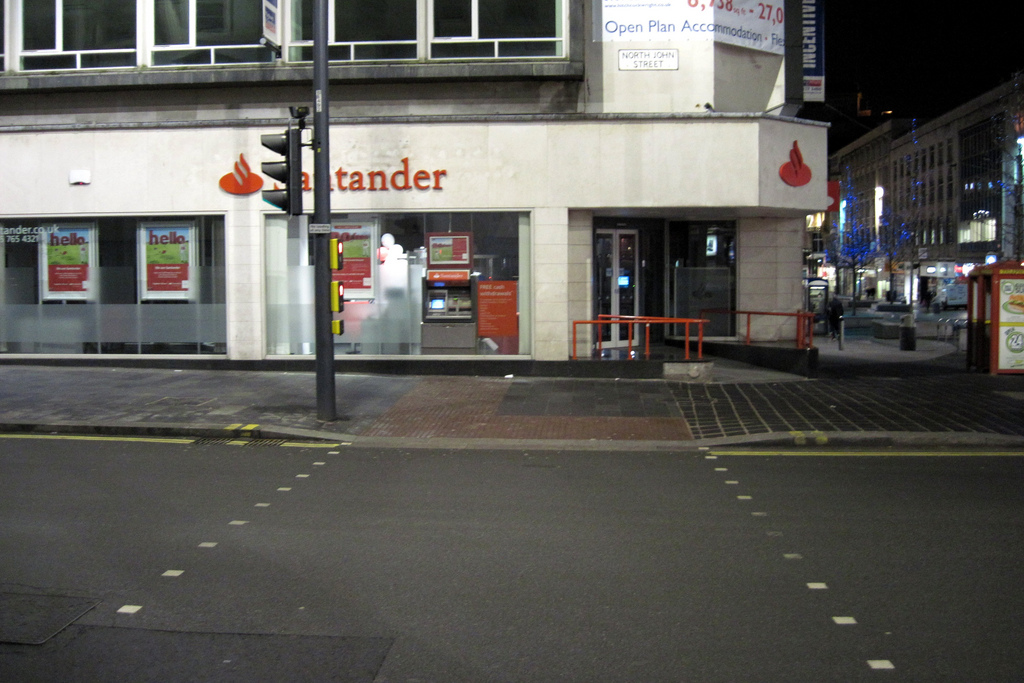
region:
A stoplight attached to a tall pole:
[253, 119, 305, 225]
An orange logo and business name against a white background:
[209, 149, 453, 200]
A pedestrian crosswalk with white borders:
[133, 430, 909, 672]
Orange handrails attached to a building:
[573, 310, 713, 371]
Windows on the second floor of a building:
[2, 1, 573, 60]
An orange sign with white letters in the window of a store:
[471, 274, 519, 354]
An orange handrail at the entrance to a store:
[716, 301, 825, 355]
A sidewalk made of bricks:
[0, 354, 1022, 452]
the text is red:
[280, 156, 446, 191]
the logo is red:
[779, 140, 809, 188]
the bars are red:
[563, 314, 701, 359]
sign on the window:
[137, 227, 195, 298]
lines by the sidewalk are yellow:
[122, 419, 315, 473]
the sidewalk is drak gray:
[48, 361, 368, 425]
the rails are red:
[589, 298, 736, 390]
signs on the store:
[38, 220, 234, 341]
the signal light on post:
[251, 98, 356, 269]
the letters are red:
[216, 137, 474, 214]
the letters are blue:
[601, 17, 778, 49]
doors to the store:
[594, 224, 665, 345]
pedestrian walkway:
[109, 440, 894, 679]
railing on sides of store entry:
[573, 307, 833, 353]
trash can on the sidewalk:
[891, 320, 921, 353]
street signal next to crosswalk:
[263, 118, 306, 223]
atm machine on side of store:
[418, 272, 475, 358]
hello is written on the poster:
[141, 223, 198, 247]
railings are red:
[564, 307, 703, 371]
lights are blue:
[832, 172, 882, 272]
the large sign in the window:
[35, 216, 100, 308]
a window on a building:
[20, 2, 56, 54]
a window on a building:
[55, 1, 154, 52]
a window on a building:
[143, 7, 189, 49]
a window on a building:
[189, 4, 288, 39]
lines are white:
[718, 429, 875, 655]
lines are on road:
[718, 418, 922, 678]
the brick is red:
[691, 370, 925, 459]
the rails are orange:
[556, 278, 835, 383]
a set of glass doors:
[559, 209, 676, 380]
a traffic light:
[249, 85, 349, 237]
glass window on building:
[25, 54, 79, 71]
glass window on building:
[79, 48, 137, 65]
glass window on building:
[151, 45, 216, 62]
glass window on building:
[217, 42, 276, 61]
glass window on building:
[354, 42, 413, 56]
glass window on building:
[432, 44, 499, 55]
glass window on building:
[499, 41, 556, 58]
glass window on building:
[479, 3, 559, 42]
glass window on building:
[433, 0, 478, 42]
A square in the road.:
[830, 607, 851, 624]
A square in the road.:
[806, 571, 832, 590]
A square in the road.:
[767, 522, 791, 542]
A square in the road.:
[751, 501, 777, 517]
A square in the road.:
[739, 494, 752, 501]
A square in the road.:
[723, 475, 739, 485]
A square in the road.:
[716, 463, 726, 470]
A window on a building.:
[442, 4, 566, 53]